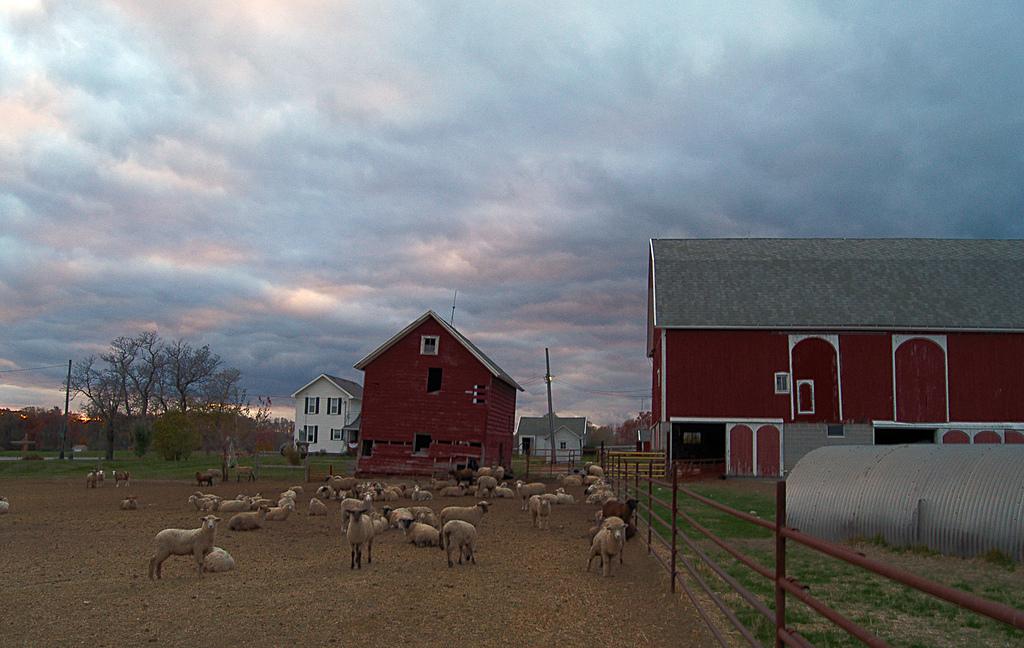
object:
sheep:
[150, 514, 226, 582]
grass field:
[0, 475, 734, 648]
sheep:
[228, 505, 271, 531]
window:
[421, 335, 441, 356]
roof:
[649, 238, 1022, 329]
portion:
[273, 286, 341, 317]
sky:
[0, 0, 1022, 435]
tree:
[151, 409, 198, 461]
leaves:
[194, 344, 229, 371]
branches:
[184, 361, 223, 414]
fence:
[602, 452, 1023, 647]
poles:
[775, 481, 786, 626]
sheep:
[120, 495, 140, 511]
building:
[288, 373, 362, 458]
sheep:
[602, 498, 640, 541]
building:
[353, 309, 525, 478]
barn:
[646, 238, 1023, 478]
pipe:
[781, 529, 1024, 628]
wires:
[58, 359, 71, 459]